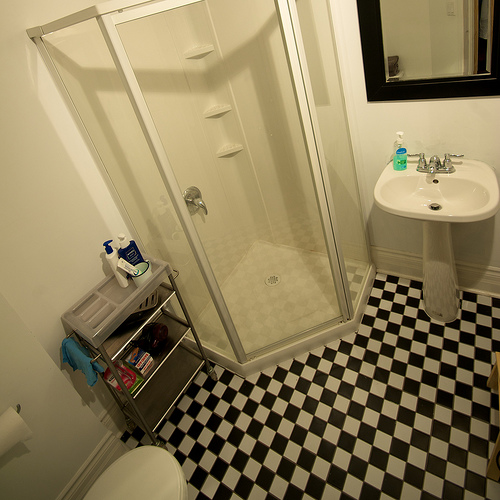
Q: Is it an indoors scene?
A: Yes, it is indoors.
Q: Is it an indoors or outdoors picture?
A: It is indoors.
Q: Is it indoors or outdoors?
A: It is indoors.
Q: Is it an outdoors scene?
A: No, it is indoors.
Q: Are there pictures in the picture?
A: No, there are no pictures.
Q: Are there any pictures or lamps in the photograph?
A: No, there are no pictures or lamps.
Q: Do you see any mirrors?
A: Yes, there is a mirror.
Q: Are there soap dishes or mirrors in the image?
A: Yes, there is a mirror.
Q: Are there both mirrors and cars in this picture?
A: No, there is a mirror but no cars.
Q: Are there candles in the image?
A: No, there are no candles.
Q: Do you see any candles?
A: No, there are no candles.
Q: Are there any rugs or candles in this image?
A: No, there are no candles or rugs.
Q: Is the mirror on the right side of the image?
A: Yes, the mirror is on the right of the image.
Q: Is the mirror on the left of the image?
A: No, the mirror is on the right of the image.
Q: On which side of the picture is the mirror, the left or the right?
A: The mirror is on the right of the image.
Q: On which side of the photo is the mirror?
A: The mirror is on the right of the image.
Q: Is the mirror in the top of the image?
A: Yes, the mirror is in the top of the image.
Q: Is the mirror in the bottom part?
A: No, the mirror is in the top of the image.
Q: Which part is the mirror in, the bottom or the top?
A: The mirror is in the top of the image.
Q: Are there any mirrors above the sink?
A: Yes, there is a mirror above the sink.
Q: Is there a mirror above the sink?
A: Yes, there is a mirror above the sink.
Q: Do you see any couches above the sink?
A: No, there is a mirror above the sink.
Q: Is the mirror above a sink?
A: Yes, the mirror is above a sink.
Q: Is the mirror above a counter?
A: No, the mirror is above a sink.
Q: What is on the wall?
A: The mirror is on the wall.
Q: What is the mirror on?
A: The mirror is on the wall.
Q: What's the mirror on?
A: The mirror is on the wall.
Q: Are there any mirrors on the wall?
A: Yes, there is a mirror on the wall.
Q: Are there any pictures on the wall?
A: No, there is a mirror on the wall.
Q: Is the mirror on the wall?
A: Yes, the mirror is on the wall.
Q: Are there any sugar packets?
A: No, there are no sugar packets.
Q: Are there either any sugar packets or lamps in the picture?
A: No, there are no sugar packets or lamps.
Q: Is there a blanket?
A: No, there are no blankets.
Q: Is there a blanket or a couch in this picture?
A: No, there are no blankets or couches.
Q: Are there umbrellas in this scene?
A: No, there are no umbrellas.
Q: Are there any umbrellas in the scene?
A: No, there are no umbrellas.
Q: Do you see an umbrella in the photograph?
A: No, there are no umbrellas.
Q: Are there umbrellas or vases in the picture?
A: No, there are no umbrellas or vases.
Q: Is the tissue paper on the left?
A: Yes, the tissue paper is on the left of the image.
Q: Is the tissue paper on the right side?
A: No, the tissue paper is on the left of the image.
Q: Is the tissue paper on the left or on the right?
A: The tissue paper is on the left of the image.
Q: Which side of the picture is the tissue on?
A: The tissue is on the left of the image.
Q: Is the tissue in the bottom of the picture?
A: Yes, the tissue is in the bottom of the image.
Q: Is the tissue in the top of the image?
A: No, the tissue is in the bottom of the image.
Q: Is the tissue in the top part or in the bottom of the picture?
A: The tissue is in the bottom of the image.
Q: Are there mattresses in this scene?
A: No, there are no mattresses.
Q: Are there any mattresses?
A: No, there are no mattresses.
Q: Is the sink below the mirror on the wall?
A: Yes, the sink is below the mirror.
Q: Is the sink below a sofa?
A: No, the sink is below the mirror.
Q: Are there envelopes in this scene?
A: No, there are no envelopes.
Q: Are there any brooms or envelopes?
A: No, there are no envelopes or brooms.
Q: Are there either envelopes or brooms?
A: No, there are no envelopes or brooms.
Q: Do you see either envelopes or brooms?
A: No, there are no envelopes or brooms.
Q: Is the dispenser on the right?
A: Yes, the dispenser is on the right of the image.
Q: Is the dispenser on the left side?
A: No, the dispenser is on the right of the image.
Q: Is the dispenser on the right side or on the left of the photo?
A: The dispenser is on the right of the image.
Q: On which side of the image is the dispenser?
A: The dispenser is on the right of the image.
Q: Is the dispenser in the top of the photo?
A: Yes, the dispenser is in the top of the image.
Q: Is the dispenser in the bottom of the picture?
A: No, the dispenser is in the top of the image.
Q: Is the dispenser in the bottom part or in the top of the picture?
A: The dispenser is in the top of the image.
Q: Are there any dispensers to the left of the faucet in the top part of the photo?
A: Yes, there is a dispenser to the left of the faucet.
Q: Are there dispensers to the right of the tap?
A: No, the dispenser is to the left of the tap.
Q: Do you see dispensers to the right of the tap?
A: No, the dispenser is to the left of the tap.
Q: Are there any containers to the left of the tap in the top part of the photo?
A: No, there is a dispenser to the left of the tap.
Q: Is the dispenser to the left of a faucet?
A: Yes, the dispenser is to the left of a faucet.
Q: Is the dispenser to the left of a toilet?
A: No, the dispenser is to the left of a faucet.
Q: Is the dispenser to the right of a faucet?
A: No, the dispenser is to the left of a faucet.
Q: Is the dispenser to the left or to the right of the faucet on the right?
A: The dispenser is to the left of the faucet.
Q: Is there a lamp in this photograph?
A: No, there are no lamps.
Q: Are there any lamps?
A: No, there are no lamps.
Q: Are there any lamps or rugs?
A: No, there are no lamps or rugs.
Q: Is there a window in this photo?
A: Yes, there is a window.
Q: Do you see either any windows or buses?
A: Yes, there is a window.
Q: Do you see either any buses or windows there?
A: Yes, there is a window.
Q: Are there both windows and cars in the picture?
A: No, there is a window but no cars.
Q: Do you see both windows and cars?
A: No, there is a window but no cars.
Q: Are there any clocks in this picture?
A: No, there are no clocks.